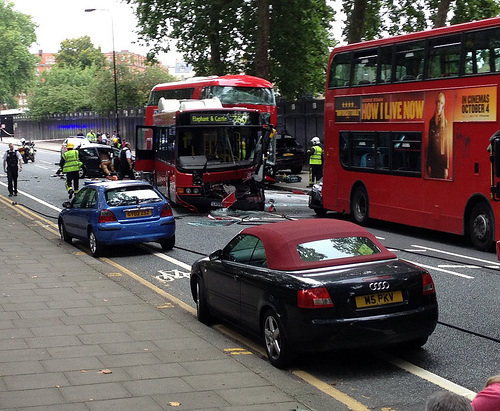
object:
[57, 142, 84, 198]
man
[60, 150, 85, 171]
vest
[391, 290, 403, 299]
yellow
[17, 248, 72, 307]
gray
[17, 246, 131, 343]
sidewalk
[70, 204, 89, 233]
blue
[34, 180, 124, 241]
parked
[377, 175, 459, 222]
red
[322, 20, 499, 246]
bus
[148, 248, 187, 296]
whit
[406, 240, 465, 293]
street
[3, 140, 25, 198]
policeman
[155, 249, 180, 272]
white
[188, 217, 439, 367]
car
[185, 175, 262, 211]
damage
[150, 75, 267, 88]
roof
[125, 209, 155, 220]
plat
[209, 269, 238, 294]
black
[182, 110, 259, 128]
banner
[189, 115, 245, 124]
lettering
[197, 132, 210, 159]
woman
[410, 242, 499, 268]
lines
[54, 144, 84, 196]
worker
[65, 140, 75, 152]
helmet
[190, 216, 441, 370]
hatchback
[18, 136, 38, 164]
motorcycle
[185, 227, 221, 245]
road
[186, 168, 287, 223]
wrecked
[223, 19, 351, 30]
full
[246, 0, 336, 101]
trees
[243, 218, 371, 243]
top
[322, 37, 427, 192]
double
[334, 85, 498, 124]
ad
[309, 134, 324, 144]
hat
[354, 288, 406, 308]
plate